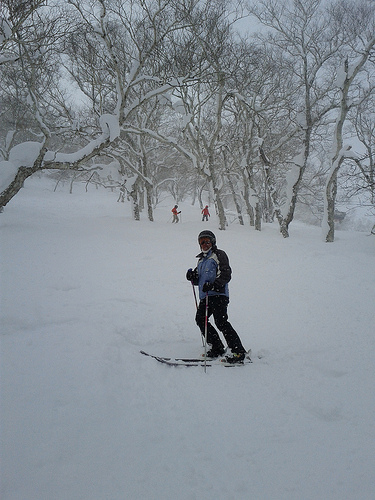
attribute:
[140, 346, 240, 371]
skis — snow covered, dark colored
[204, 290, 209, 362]
ski pole — red, white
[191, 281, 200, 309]
ski pole — red, white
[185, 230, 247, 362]
man — skiing, leaning, skidding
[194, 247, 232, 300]
jacket — black, white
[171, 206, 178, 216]
jacket — red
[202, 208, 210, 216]
jacket — red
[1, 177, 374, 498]
snow — white, clean, messy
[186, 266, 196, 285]
glove — black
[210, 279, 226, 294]
glove — black